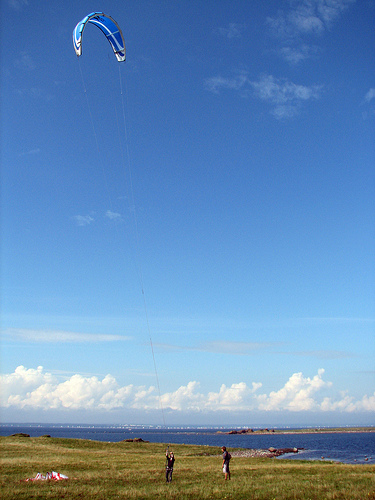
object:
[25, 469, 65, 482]
kite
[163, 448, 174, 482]
man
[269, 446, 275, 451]
rocks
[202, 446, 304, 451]
shore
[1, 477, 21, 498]
grass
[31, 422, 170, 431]
bridge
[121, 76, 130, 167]
string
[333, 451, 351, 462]
water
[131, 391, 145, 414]
clouds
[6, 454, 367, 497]
field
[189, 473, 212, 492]
grass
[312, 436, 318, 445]
water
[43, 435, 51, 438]
rocks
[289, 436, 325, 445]
water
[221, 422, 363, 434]
island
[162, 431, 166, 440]
water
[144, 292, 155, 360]
line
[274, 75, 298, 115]
cloud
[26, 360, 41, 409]
clouds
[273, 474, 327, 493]
grass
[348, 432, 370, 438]
water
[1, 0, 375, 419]
sky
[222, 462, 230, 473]
shorts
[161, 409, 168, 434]
string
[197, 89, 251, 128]
air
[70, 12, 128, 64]
kite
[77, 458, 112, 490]
ground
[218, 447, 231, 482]
man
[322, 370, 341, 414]
clouds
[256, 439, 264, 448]
water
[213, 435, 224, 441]
water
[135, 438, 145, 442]
rock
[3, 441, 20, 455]
grass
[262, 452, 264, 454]
gravel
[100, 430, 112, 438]
water